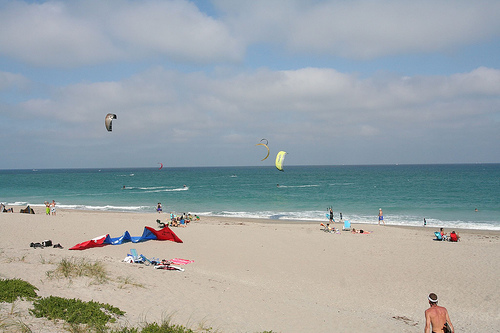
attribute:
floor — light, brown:
[204, 237, 489, 331]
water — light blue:
[3, 164, 499, 227]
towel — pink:
[168, 256, 193, 267]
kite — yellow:
[269, 146, 293, 170]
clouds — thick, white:
[0, 0, 498, 166]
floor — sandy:
[10, 202, 465, 331]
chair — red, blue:
[125, 247, 153, 263]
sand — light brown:
[0, 203, 498, 331]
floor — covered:
[3, 208, 499, 332]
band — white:
[424, 295, 440, 302]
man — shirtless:
[409, 292, 458, 330]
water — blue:
[376, 173, 473, 205]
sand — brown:
[244, 275, 326, 308]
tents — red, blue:
[83, 221, 172, 248]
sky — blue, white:
[216, 51, 498, 122]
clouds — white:
[6, 4, 496, 65]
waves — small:
[4, 193, 158, 214]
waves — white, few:
[131, 175, 192, 205]